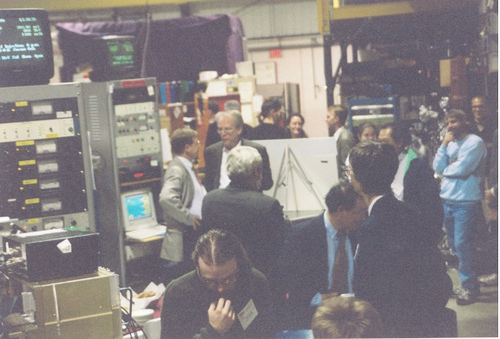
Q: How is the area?
A: Crowded.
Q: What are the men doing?
A: Talking.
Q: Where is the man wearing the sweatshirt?
A: On the right.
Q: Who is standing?
A: Everyone.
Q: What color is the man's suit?
A: Black.